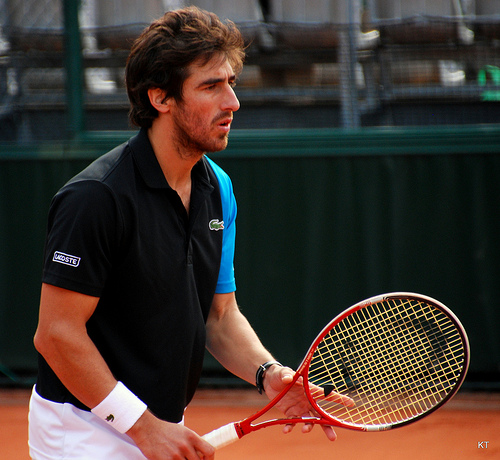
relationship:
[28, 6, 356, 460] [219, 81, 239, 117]
player has a nose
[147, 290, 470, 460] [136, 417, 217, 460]
racket in hand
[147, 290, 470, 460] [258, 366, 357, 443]
racket in hand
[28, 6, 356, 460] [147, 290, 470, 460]
player holding racket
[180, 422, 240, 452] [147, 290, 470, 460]
handle of racket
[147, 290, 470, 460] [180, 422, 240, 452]
racket has a handle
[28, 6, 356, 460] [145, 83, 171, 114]
player has an ear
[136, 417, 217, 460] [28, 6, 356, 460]
hand of player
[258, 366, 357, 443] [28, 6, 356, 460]
hand of player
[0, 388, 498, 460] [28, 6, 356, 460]
ground below player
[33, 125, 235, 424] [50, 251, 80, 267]
shirt has a word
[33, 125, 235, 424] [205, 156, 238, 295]
shirt has a sleeve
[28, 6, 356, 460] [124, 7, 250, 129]
man has hair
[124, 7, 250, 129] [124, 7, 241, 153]
hair on head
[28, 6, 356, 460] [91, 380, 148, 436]
player wearing a wristband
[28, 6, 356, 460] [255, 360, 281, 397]
player wearing a wristwatch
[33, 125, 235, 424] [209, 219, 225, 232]
shirt has a logo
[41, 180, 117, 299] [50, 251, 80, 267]
sleeve has a logo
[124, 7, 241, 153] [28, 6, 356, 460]
head of a man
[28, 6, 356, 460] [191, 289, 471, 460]
player playing tennis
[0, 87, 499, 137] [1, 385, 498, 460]
seat at ten court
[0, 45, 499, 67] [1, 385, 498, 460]
seat at ten court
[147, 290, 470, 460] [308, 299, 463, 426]
racket has strings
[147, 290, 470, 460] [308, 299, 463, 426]
racket has wires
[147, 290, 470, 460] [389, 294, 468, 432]
racket has portion of black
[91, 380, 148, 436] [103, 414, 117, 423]
sweatband has a logo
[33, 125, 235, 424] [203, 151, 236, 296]
shirt has blue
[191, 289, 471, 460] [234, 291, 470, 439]
tennis racket red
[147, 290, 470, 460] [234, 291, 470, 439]
racket has red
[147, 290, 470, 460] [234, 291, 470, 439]
racket with red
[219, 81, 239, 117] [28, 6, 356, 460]
nose of man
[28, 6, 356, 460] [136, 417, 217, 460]
man has a hand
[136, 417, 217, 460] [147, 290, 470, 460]
hand holding racket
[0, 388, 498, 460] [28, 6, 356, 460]
ground under man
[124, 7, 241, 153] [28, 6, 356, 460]
head of man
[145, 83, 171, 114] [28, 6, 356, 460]
ear of man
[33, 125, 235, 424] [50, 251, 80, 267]
shirt has writing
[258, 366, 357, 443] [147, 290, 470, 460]
hand on racket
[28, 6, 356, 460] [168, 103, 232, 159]
man has a beard